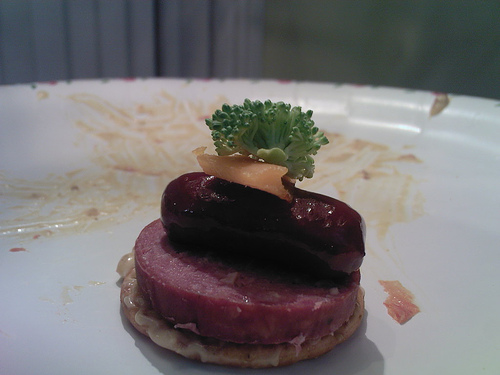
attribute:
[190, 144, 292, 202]
cheese — yellow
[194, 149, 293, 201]
cheese — small, sliced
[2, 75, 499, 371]
plate — white, large, paper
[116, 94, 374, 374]
hors d'oeuvre — small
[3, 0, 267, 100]
blinds — white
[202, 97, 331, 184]
broccoli — green, small, uncooked, piece, raw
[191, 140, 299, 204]
cheese — yellow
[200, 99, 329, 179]
vegetable — green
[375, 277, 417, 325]
sauce — red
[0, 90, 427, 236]
stain — brown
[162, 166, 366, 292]
sausage — brown, small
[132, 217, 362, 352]
meat slice — pink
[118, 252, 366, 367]
cracker — white, brown, crispy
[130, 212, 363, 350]
meat — sliced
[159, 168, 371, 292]
meat — dark red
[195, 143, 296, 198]
cheese piece — small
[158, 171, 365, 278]
ham — red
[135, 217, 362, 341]
meat — pink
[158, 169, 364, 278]
hot dog — mini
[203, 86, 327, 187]
broccoli — green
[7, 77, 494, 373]
dish — white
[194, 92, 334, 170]
broccoli — green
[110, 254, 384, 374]
cracker — round